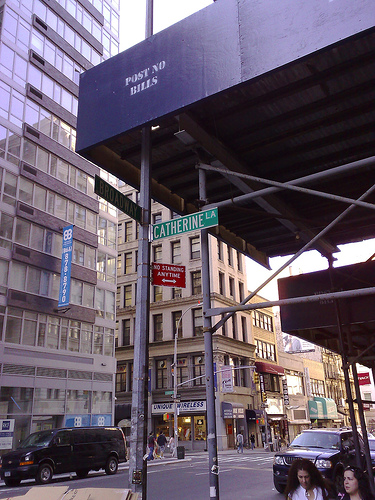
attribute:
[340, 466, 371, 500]
couple — talking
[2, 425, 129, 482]
van — parked, black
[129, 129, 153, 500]
pole — metal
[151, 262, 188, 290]
sign — red, white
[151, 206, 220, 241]
street sign — green, green ad white, white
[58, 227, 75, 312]
sign — blue, business promotional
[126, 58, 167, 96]
letters — white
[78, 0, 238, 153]
banner — blue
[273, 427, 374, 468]
truck — parked, black, dark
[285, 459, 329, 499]
woman — talking, walking, long, curly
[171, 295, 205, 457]
light — tall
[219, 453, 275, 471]
paint — white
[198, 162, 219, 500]
poles — metal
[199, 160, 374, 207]
scaffolding — grey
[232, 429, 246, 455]
pedestrian — crossing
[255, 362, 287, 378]
awning — dark red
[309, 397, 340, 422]
overhang — green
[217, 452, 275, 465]
crosswalk — painted white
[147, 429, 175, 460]
people — walking